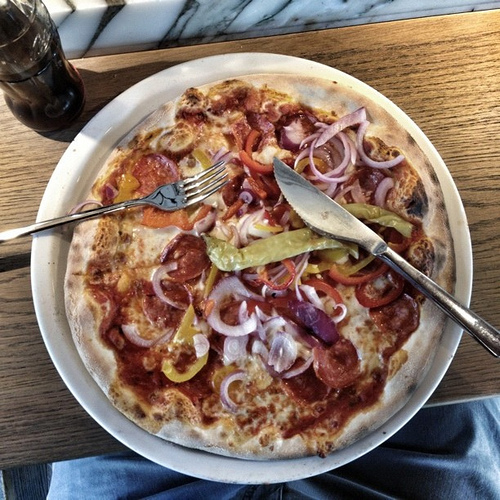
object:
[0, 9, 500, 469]
counter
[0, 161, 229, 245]
fork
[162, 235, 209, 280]
pepperoni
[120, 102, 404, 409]
onion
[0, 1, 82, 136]
bottle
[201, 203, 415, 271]
pepper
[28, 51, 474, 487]
pan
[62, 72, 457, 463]
pizza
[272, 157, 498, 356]
knife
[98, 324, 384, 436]
sauce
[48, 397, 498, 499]
cloth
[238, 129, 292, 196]
peppers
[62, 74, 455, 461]
cheese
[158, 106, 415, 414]
veggies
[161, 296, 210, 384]
peppers